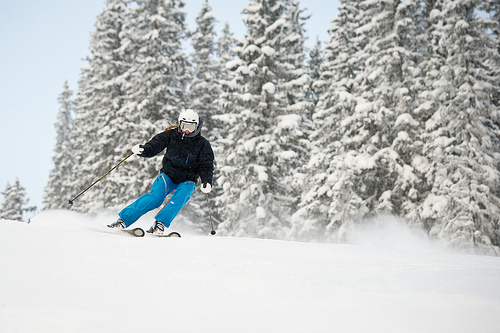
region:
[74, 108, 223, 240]
th person skiing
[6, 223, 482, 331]
the white snow on the ground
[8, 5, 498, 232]
the trees covered with snow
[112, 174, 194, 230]
the blue pants on the skier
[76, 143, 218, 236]
the ski poles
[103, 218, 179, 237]
the skis on the skiers feet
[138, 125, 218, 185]
the dark jacket on the skier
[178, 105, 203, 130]
the white helmet on the skier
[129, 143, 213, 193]
the white gloves on the skiers hands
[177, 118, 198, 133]
the eye protector on the skiers face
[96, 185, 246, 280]
Skis on the snow.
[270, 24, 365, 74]
Snow covered trees.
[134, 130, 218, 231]
Blue ski pants.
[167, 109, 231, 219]
White helmet and goggles on skier.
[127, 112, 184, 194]
White gloves on skier.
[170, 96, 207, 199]
White helmet on skier.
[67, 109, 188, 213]
Black ski poles being used.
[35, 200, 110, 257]
White snow on the ground.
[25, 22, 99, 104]
Gray skies in the background.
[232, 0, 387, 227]
Pine trees in the background.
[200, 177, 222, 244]
A skating stick for breaking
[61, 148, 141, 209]
A skating stick for breaking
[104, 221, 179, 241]
A skatting board with shoes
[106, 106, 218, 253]
Alady playing the skatting game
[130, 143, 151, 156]
White gloves for skatting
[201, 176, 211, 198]
White gloves for skatting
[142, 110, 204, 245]
Protective skatting gear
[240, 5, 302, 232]
A tree covered by snow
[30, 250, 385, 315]
Ground covered with snow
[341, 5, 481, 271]
Trees covered with snow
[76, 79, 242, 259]
A skier on a snowy hill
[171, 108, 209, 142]
a white helmet and white goggles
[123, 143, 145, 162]
white gloves on hands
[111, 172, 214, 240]
light blue ski pants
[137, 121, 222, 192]
black jacket worn by skier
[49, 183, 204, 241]
puffs of snow kicked up by skier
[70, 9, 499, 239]
many trees covered in snow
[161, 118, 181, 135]
little bit of skiers blond hair on shoulder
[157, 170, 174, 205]
a silver zipper on front of pants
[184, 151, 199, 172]
a small blue line on black jacket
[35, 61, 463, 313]
A man skiing down a mountain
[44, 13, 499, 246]
Trees behind the skier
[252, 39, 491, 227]
Snow is covering the trees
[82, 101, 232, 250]
A skier in the snow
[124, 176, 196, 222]
Blue pants on the man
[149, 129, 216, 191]
A black jacket on the man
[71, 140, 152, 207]
A skipole in the man's hand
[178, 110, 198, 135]
A white helmet on the man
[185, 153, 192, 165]
Blue stripe on the jacket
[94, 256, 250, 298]
Fluffy white snow on the ground